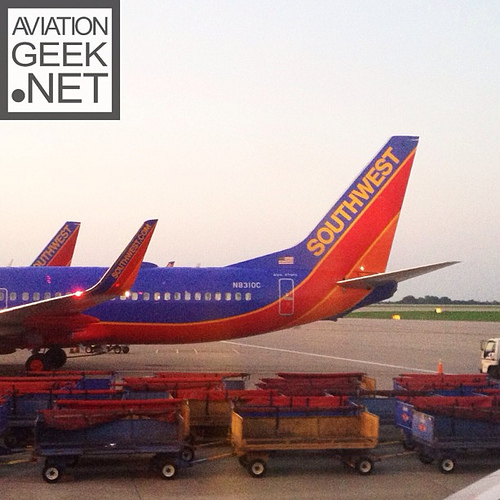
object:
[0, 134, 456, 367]
plane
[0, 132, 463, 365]
airplane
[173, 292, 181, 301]
windows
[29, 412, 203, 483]
suv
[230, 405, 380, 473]
cart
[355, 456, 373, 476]
wheels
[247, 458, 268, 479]
wheel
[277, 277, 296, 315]
door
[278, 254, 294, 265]
flag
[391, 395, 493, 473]
cart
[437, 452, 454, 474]
wheels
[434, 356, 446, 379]
cone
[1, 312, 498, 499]
runway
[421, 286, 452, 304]
trees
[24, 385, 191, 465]
wagons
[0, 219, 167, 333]
wings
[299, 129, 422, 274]
tailfin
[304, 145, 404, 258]
word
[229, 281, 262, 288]
number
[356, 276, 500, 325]
forest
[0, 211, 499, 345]
distance